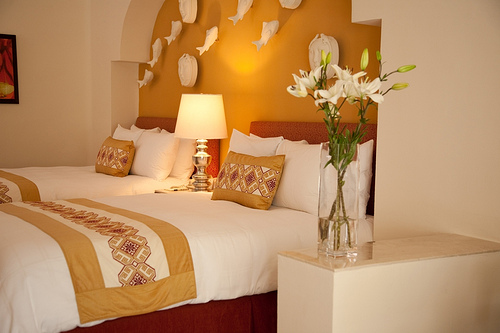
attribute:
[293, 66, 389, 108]
lillies — white, green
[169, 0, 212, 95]
masks — white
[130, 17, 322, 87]
wall — yellow, orange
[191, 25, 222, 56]
fish — white, ceramic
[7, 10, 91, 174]
wall — white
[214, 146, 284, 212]
pillow — colorful, tan, brown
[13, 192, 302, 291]
comforter — white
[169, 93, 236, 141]
lamp shade — white, illuminated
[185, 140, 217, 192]
base — silver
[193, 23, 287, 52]
art — ceramic, white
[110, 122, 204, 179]
pillows — white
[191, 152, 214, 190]
lamp stand — silver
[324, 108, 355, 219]
stems — green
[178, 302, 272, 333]
bed curtain — red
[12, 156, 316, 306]
beds — twin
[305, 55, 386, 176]
flowers — white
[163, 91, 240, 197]
lamp — on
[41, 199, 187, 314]
border — gold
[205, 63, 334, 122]
alcove — gold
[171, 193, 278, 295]
bedsheets — white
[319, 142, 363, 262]
vase — glass, clear, tall